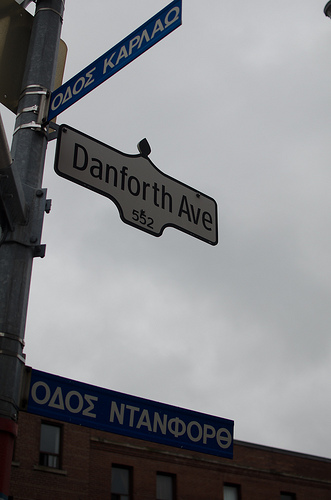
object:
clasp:
[13, 123, 42, 136]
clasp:
[15, 105, 38, 119]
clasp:
[18, 90, 47, 100]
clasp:
[20, 84, 46, 94]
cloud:
[25, 0, 331, 460]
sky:
[30, 0, 331, 460]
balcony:
[33, 418, 67, 475]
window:
[155, 469, 177, 499]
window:
[221, 480, 242, 499]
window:
[278, 491, 297, 499]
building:
[11, 409, 331, 500]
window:
[110, 463, 135, 499]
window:
[40, 421, 63, 470]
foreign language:
[27, 368, 234, 458]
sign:
[25, 362, 234, 458]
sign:
[53, 122, 218, 247]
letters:
[50, 6, 180, 111]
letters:
[72, 142, 213, 232]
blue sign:
[45, 0, 182, 122]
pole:
[0, 0, 66, 418]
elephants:
[53, 123, 218, 247]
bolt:
[44, 199, 52, 214]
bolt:
[33, 244, 46, 258]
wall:
[11, 409, 331, 500]